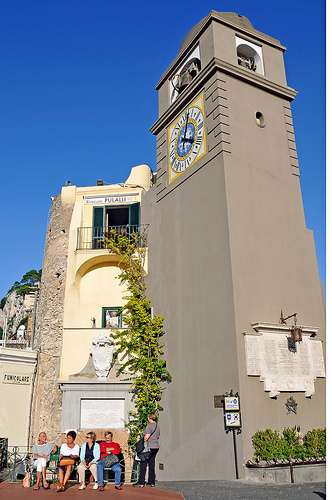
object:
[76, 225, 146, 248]
railing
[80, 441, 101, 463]
sweater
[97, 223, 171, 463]
vine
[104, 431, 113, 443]
head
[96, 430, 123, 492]
man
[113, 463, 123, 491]
leg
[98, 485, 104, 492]
shoes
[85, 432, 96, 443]
head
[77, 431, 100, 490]
woman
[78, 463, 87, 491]
leg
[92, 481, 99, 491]
white shoe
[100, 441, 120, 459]
red shirt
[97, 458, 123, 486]
blue jeans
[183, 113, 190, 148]
black hands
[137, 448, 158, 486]
black pants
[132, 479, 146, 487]
clogs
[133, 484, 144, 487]
soles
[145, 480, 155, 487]
clogs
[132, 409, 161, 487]
woman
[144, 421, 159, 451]
grey top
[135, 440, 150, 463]
crossbody bag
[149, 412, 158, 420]
blonde hair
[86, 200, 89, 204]
word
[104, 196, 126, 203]
pulalli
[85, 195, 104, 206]
ristorante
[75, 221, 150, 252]
small balcony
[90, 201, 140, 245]
wine bar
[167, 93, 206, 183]
clock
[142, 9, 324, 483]
building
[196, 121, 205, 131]
roman numeral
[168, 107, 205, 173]
clock face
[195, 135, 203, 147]
roman numeral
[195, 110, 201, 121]
roman numeral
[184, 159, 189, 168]
roman numeral